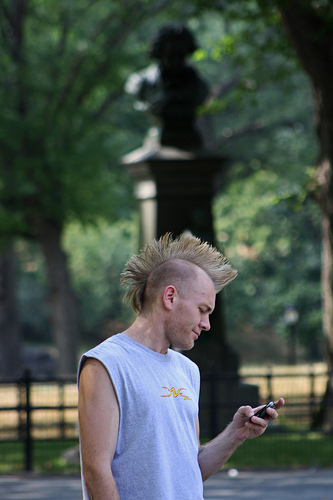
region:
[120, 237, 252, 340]
the head of a man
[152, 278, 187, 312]
the ear of a man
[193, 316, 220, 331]
the nose of a man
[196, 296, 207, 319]
the eye of a man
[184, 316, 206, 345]
the mouth of a man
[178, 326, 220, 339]
the lips of a man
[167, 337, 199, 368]
the chin of a man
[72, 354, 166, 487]
the arm of a man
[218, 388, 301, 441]
the hand of a man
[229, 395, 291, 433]
the fingers of a man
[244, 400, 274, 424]
A cell phone in a persons hand.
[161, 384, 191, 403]
The simple yellow design on a shirt.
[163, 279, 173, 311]
The right ear of a person.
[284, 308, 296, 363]
A very blurry street lamp.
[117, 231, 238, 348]
The head of a person.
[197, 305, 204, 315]
The right eye of a person.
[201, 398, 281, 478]
The hand of a person holding a cell phone.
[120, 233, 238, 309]
A persons hair cut like a mohawk.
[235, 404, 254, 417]
The thumb of a person.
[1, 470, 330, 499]
A blurry area of pavement.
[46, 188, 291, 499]
man has a mohawk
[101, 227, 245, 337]
man's mohawk is blonde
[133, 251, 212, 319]
man's head is shaved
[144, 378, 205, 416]
yellow letters on shirt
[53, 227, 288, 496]
man looking at phone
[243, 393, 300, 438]
the phone is black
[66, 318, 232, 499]
man's shirt is gray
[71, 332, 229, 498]
the shirt is sleeveless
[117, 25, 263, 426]
large statue behind the man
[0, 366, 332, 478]
black railing behind the man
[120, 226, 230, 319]
mohawk hairstyle on young man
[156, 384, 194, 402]
yellow tee shirt graphics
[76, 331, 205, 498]
sleeveless gray tee shirt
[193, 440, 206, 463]
tattoo on left arm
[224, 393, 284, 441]
left hand holding a phone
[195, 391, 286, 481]
holding a cell phone in left arm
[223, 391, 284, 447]
texting with the left hand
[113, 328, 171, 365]
crewneck of gray tee shirt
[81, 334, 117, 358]
right shoulder seam of gray tee shirt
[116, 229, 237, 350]
right side facial profile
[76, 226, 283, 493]
man with a mohalk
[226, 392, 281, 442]
cell phone in the man's left hand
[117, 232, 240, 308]
mohawk hair cut on the man's head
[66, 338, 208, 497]
gray tank top with a yellow symbol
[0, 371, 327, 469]
black fence in the background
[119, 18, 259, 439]
tall statue behind the fence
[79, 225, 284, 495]
a man looking down at his phone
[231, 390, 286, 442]
the man is texting on his cellphone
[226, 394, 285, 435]
small black phone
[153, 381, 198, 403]
red and yellow symbol on the man's shirt